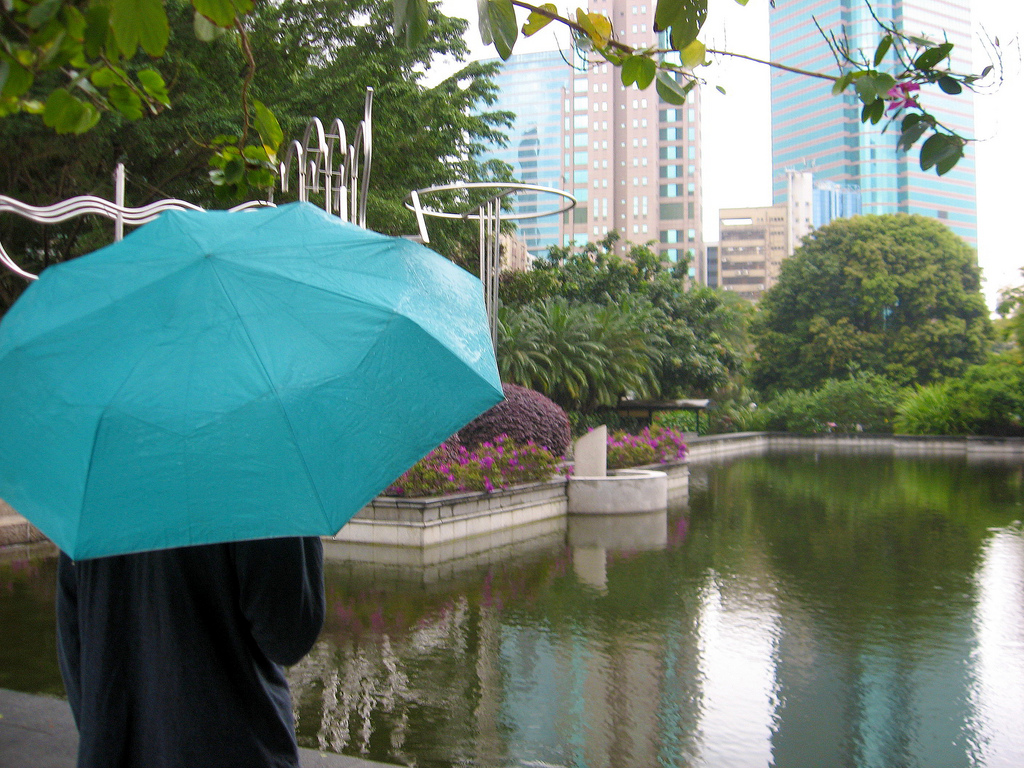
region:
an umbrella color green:
[0, 188, 517, 584]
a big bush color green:
[752, 195, 1010, 405]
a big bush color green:
[490, 232, 747, 414]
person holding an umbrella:
[12, 179, 537, 765]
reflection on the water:
[398, 540, 1009, 741]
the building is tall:
[757, 3, 996, 261]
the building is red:
[546, 6, 721, 282]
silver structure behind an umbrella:
[0, 63, 416, 327]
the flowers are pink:
[599, 412, 699, 489]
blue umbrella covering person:
[4, 199, 499, 561]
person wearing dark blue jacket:
[50, 532, 330, 766]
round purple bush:
[460, 382, 572, 468]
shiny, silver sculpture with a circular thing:
[4, 88, 583, 401]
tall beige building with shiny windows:
[556, 1, 709, 284]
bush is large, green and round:
[754, 208, 995, 430]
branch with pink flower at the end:
[475, 3, 1020, 180]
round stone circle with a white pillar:
[565, 423, 668, 510]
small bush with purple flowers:
[587, 423, 692, 471]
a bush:
[794, 238, 944, 368]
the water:
[671, 602, 881, 736]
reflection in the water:
[787, 482, 959, 616]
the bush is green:
[813, 235, 930, 357]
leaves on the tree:
[22, 16, 169, 162]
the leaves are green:
[51, 29, 166, 141]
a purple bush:
[505, 387, 562, 444]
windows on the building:
[784, 93, 838, 164]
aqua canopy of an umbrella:
[2, 202, 500, 561]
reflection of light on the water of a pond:
[686, 461, 1022, 766]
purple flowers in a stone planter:
[460, 426, 695, 534]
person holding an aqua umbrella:
[2, 202, 502, 766]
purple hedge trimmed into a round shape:
[455, 379, 573, 468]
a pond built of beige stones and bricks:
[378, 483, 557, 547]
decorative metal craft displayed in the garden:
[2, 75, 382, 213]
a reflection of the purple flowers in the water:
[322, 538, 598, 751]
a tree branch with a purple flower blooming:
[458, 3, 1019, 174]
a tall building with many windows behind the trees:
[768, 0, 980, 219]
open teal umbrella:
[0, 201, 507, 557]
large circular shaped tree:
[743, 207, 988, 439]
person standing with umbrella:
[0, 204, 510, 765]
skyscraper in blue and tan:
[769, 0, 976, 247]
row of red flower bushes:
[601, 422, 688, 474]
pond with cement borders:
[4, 427, 1022, 766]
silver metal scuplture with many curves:
[269, 83, 375, 229]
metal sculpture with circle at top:
[397, 168, 574, 333]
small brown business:
[710, 203, 793, 309]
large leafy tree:
[491, 288, 670, 415]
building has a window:
[657, 151, 668, 164]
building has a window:
[669, 161, 682, 177]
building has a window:
[656, 178, 669, 197]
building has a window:
[671, 182, 684, 199]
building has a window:
[657, 197, 683, 217]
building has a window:
[656, 223, 669, 243]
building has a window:
[674, 223, 684, 243]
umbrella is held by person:
[17, 177, 482, 595]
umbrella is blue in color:
[17, 198, 520, 549]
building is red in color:
[722, 183, 806, 302]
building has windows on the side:
[722, 233, 765, 285]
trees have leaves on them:
[26, 19, 359, 171]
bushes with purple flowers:
[497, 367, 587, 457]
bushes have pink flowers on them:
[605, 423, 704, 469]